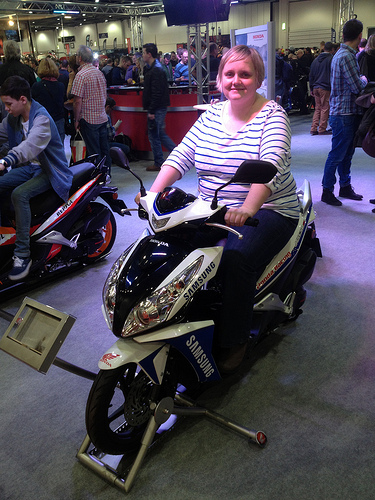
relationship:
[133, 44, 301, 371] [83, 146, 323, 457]
woman on vehicle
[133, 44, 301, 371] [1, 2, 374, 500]
woman at convention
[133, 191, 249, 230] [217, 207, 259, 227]
hands gripping handlebars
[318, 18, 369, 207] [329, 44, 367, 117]
man in shirt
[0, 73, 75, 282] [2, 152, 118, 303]
boy on scooter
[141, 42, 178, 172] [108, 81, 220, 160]
man in front of partition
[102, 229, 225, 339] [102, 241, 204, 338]
panel has headlights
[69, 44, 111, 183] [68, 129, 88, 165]
man carrying bag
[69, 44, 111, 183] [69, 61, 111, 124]
man in shirt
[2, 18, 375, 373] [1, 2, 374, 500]
people at convention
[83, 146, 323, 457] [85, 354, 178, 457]
vehicle has wheel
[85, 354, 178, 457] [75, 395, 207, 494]
wheel has lock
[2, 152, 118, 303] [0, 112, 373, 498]
scooter on floor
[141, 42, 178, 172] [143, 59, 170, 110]
man in jacket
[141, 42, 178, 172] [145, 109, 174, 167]
man wearing jeans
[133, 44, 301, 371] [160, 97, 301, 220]
woman wearing shirt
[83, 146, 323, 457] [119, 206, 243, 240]
vehicle has break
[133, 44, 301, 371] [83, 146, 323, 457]
woman sitting on vehicle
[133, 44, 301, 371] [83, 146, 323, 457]
woman drives vehicle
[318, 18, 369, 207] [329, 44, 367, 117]
man wearing shirt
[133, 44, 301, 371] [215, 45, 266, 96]
woman has hair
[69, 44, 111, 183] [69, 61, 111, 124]
man wearing shirt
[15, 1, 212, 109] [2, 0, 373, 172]
railing in background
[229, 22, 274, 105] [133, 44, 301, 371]
sign behind woman